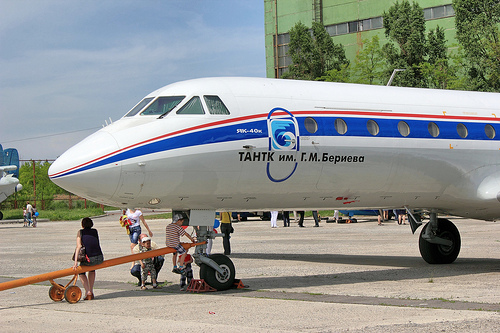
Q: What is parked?
A: Airplane.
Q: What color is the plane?
A: White.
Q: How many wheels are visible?
A: Two.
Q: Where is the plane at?
A: Airport lot.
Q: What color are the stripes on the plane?
A: Blue and red.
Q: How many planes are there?
A: One.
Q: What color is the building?
A: Green.